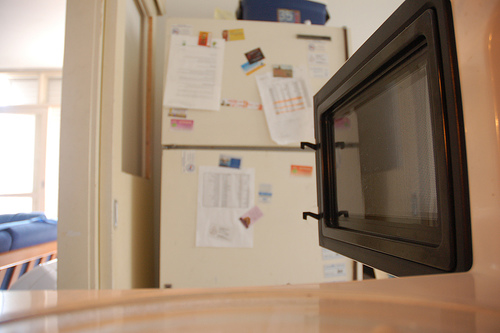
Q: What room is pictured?
A: It is a kitchen.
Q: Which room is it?
A: It is a kitchen.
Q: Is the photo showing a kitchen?
A: Yes, it is showing a kitchen.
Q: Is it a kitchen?
A: Yes, it is a kitchen.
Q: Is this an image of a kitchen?
A: Yes, it is showing a kitchen.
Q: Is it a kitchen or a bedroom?
A: It is a kitchen.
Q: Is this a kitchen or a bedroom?
A: It is a kitchen.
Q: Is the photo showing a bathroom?
A: No, the picture is showing a kitchen.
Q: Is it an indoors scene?
A: Yes, it is indoors.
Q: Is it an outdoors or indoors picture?
A: It is indoors.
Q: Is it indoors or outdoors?
A: It is indoors.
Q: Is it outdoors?
A: No, it is indoors.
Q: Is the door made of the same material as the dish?
A: Yes, both the door and the dish are made of glass.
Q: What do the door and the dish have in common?
A: The material, both the door and the dish are glass.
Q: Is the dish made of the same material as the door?
A: Yes, both the dish and the door are made of glass.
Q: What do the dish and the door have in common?
A: The material, both the dish and the door are glass.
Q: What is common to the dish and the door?
A: The material, both the dish and the door are glass.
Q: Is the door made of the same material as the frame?
A: No, the door is made of glass and the frame is made of wood.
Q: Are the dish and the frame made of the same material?
A: No, the dish is made of glass and the frame is made of wood.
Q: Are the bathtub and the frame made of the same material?
A: No, the bathtub is made of plastic and the frame is made of wood.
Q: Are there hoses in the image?
A: No, there are no hoses.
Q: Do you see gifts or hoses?
A: No, there are no hoses or gifts.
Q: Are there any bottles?
A: No, there are no bottles.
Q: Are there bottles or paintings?
A: No, there are no bottles or paintings.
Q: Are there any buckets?
A: No, there are no buckets.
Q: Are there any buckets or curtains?
A: No, there are no buckets or curtains.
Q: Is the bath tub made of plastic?
A: Yes, the bath tub is made of plastic.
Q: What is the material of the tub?
A: The tub is made of plastic.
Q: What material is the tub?
A: The tub is made of plastic.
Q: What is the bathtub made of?
A: The tub is made of plastic.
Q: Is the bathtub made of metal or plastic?
A: The bathtub is made of plastic.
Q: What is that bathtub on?
A: The bathtub is on the refrigerator.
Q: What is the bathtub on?
A: The bathtub is on the refrigerator.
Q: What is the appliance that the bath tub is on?
A: The appliance is a refrigerator.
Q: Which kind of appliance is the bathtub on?
A: The bath tub is on the refrigerator.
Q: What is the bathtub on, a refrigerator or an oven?
A: The bathtub is on a refrigerator.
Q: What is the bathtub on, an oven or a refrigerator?
A: The bathtub is on a refrigerator.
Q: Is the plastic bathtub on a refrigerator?
A: Yes, the bath tub is on a refrigerator.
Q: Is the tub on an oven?
A: No, the tub is on a refrigerator.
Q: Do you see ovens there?
A: No, there are no ovens.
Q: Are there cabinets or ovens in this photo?
A: No, there are no ovens or cabinets.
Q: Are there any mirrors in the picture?
A: No, there are no mirrors.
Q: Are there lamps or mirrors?
A: No, there are no mirrors or lamps.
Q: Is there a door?
A: Yes, there is a door.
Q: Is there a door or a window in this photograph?
A: Yes, there is a door.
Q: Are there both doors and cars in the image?
A: No, there is a door but no cars.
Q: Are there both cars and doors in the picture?
A: No, there is a door but no cars.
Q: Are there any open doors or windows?
A: Yes, there is an open door.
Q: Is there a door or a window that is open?
A: Yes, the door is open.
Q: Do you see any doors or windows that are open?
A: Yes, the door is open.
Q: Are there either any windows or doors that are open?
A: Yes, the door is open.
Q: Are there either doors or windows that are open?
A: Yes, the door is open.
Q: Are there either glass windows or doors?
A: Yes, there is a glass door.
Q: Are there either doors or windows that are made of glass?
A: Yes, the door is made of glass.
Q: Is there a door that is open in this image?
A: Yes, there is an open door.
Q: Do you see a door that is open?
A: Yes, there is a door that is open.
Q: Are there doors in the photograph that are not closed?
A: Yes, there is a open door.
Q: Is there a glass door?
A: Yes, there is a door that is made of glass.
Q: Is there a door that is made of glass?
A: Yes, there is a door that is made of glass.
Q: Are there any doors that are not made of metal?
A: Yes, there is a door that is made of glass.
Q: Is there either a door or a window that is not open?
A: No, there is a door but it is open.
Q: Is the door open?
A: Yes, the door is open.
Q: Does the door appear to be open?
A: Yes, the door is open.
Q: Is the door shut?
A: No, the door is open.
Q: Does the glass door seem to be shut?
A: No, the door is open.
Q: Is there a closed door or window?
A: No, there is a door but it is open.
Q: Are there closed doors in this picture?
A: No, there is a door but it is open.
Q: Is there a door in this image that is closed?
A: No, there is a door but it is open.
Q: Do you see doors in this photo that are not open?
A: No, there is a door but it is open.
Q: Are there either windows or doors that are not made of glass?
A: No, there is a door but it is made of glass.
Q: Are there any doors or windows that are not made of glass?
A: No, there is a door but it is made of glass.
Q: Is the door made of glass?
A: Yes, the door is made of glass.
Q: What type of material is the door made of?
A: The door is made of glass.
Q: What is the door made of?
A: The door is made of glass.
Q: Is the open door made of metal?
A: No, the door is made of glass.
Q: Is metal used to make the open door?
A: No, the door is made of glass.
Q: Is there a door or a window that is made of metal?
A: No, there is a door but it is made of glass.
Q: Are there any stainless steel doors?
A: No, there is a door but it is made of glass.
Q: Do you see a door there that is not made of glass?
A: No, there is a door but it is made of glass.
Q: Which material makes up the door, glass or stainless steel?
A: The door is made of glass.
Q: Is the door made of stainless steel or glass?
A: The door is made of glass.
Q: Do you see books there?
A: No, there are no books.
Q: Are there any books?
A: No, there are no books.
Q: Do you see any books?
A: No, there are no books.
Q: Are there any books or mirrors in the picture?
A: No, there are no books or mirrors.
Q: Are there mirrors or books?
A: No, there are no books or mirrors.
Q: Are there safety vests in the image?
A: No, there are no safety vests.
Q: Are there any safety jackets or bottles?
A: No, there are no safety jackets or bottles.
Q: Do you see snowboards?
A: No, there are no snowboards.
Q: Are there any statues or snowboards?
A: No, there are no snowboards or statues.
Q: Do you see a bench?
A: No, there are no benches.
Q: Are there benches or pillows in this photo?
A: No, there are no benches or pillows.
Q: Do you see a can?
A: No, there are no cans.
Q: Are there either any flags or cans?
A: No, there are no cans or flags.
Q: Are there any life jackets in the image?
A: No, there are no life jackets.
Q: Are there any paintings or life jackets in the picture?
A: No, there are no life jackets or paintings.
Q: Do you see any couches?
A: Yes, there is a couch.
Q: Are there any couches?
A: Yes, there is a couch.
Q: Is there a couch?
A: Yes, there is a couch.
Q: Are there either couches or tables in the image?
A: Yes, there is a couch.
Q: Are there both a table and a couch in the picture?
A: No, there is a couch but no tables.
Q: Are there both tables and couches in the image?
A: No, there is a couch but no tables.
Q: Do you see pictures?
A: No, there are no pictures.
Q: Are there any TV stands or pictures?
A: No, there are no pictures or TV stands.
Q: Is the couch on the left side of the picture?
A: Yes, the couch is on the left of the image.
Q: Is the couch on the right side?
A: No, the couch is on the left of the image.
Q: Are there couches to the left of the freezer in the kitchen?
A: Yes, there is a couch to the left of the freezer.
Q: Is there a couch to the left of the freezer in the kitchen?
A: Yes, there is a couch to the left of the freezer.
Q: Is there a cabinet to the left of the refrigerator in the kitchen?
A: No, there is a couch to the left of the fridge.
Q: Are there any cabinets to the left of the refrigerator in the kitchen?
A: No, there is a couch to the left of the fridge.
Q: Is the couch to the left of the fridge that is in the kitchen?
A: Yes, the couch is to the left of the fridge.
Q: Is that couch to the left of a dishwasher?
A: No, the couch is to the left of the fridge.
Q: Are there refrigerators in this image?
A: Yes, there is a refrigerator.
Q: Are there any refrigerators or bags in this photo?
A: Yes, there is a refrigerator.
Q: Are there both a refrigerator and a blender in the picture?
A: No, there is a refrigerator but no blenders.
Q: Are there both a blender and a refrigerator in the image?
A: No, there is a refrigerator but no blenders.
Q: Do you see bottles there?
A: No, there are no bottles.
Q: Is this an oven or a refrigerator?
A: This is a refrigerator.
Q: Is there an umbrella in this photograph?
A: No, there are no umbrellas.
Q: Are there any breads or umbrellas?
A: No, there are no umbrellas or breads.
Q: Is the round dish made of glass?
A: Yes, the dish is made of glass.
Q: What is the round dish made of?
A: The dish is made of glass.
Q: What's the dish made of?
A: The dish is made of glass.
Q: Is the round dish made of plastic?
A: No, the dish is made of glass.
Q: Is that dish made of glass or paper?
A: The dish is made of glass.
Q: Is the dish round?
A: Yes, the dish is round.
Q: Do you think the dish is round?
A: Yes, the dish is round.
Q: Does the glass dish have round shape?
A: Yes, the dish is round.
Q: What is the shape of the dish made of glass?
A: The dish is round.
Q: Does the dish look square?
A: No, the dish is round.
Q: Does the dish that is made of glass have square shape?
A: No, the dish is round.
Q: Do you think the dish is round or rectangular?
A: The dish is round.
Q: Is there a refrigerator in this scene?
A: Yes, there is a refrigerator.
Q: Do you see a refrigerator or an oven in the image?
A: Yes, there is a refrigerator.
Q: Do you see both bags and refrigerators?
A: No, there is a refrigerator but no bags.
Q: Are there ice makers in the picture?
A: No, there are no ice makers.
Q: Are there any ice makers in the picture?
A: No, there are no ice makers.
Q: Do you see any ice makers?
A: No, there are no ice makers.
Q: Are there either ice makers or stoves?
A: No, there are no ice makers or stoves.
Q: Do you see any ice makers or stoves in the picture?
A: No, there are no ice makers or stoves.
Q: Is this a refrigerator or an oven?
A: This is a refrigerator.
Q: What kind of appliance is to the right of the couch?
A: The appliance is a refrigerator.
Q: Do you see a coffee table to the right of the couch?
A: No, there is a refrigerator to the right of the couch.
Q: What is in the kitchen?
A: The refrigerator is in the kitchen.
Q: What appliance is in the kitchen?
A: The appliance is a refrigerator.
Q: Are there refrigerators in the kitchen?
A: Yes, there is a refrigerator in the kitchen.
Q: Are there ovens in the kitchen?
A: No, there is a refrigerator in the kitchen.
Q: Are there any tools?
A: No, there are no tools.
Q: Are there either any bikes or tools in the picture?
A: No, there are no tools or bikes.